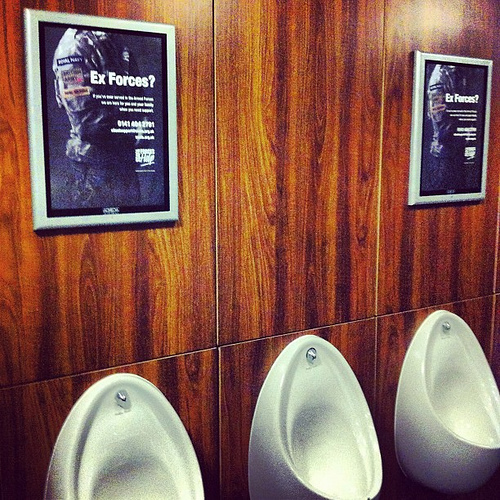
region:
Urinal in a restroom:
[237, 324, 389, 494]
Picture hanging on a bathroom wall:
[20, 9, 197, 239]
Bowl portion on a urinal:
[292, 403, 365, 473]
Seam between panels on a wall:
[208, 339, 229, 366]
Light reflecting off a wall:
[407, 13, 471, 52]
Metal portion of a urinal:
[300, 347, 332, 374]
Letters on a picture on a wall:
[80, 69, 155, 88]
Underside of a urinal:
[402, 449, 471, 491]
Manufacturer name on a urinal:
[110, 409, 139, 420]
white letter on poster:
[88, 70, 100, 82]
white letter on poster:
[96, 70, 106, 85]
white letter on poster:
[108, 70, 118, 84]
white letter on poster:
[114, 73, 120, 88]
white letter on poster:
[121, 74, 128, 84]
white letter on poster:
[129, 75, 136, 88]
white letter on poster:
[139, 74, 149, 89]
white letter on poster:
[443, 91, 450, 104]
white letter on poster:
[447, 95, 456, 102]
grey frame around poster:
[1, 17, 201, 225]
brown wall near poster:
[212, 43, 343, 187]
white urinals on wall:
[57, 295, 467, 492]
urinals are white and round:
[255, 337, 395, 495]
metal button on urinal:
[291, 348, 332, 375]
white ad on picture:
[47, 27, 177, 208]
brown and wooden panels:
[212, 18, 379, 326]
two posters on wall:
[24, 20, 482, 247]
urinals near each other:
[77, 305, 469, 496]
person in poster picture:
[30, 21, 150, 192]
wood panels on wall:
[4, 3, 498, 498]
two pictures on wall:
[23, 8, 493, 233]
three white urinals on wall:
[44, 307, 496, 498]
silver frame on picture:
[408, 51, 493, 205]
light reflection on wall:
[391, 1, 472, 41]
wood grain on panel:
[308, 31, 332, 168]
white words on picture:
[91, 70, 154, 172]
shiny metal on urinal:
[305, 349, 320, 364]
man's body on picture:
[53, 29, 148, 165]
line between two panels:
[212, 1, 217, 344]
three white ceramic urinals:
[23, 289, 497, 499]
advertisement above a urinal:
[17, 6, 205, 258]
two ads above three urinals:
[10, 4, 498, 499]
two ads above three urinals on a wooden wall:
[12, 5, 498, 497]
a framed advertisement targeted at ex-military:
[18, 5, 199, 246]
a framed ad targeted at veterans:
[14, 7, 200, 242]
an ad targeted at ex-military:
[14, 6, 216, 260]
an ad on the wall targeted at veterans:
[17, 6, 197, 247]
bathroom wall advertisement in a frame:
[15, 5, 212, 262]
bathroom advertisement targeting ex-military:
[14, 5, 235, 264]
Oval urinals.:
[59, 315, 496, 498]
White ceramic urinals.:
[45, 314, 488, 499]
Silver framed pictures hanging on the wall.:
[27, 12, 497, 234]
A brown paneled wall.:
[3, 3, 495, 498]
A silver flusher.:
[114, 388, 131, 411]